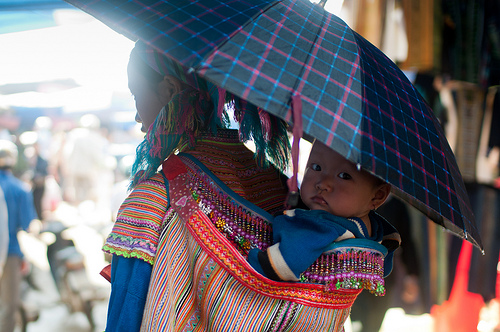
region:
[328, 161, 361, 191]
eye of the kid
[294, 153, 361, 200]
two eyes of the kid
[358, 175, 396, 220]
ear of the kid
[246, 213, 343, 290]
outfit on the kid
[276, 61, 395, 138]
umbrella above the kid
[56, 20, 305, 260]
person carrying a kid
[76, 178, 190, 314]
left arm of lady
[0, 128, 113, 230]
light in the background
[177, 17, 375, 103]
top of the umbrella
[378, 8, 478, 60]
blurry background of photo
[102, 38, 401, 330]
Woman carrying a child on her back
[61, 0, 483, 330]
Woman and a baby under an umbrella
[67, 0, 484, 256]
Plastic black umbrella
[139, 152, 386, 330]
Colorful beaded baby carrier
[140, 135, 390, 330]
Baby in a baby carrier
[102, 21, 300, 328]
Woman wearing a colorful shirt and blue sleeve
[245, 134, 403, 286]
Baby wearing a blue outfit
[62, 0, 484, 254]
Black umbrella with red and blue stripes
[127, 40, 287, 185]
Bandanna tied around a woman's head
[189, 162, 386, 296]
Fuchsia and flower beading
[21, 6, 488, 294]
mother and child under open umbrella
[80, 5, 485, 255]
blue and red plaid on black background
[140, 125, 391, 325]
baby being carried in pouch on mother's back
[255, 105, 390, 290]
baby in blue outfit with head turned to side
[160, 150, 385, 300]
colorful rows of hanging beadwork along pouch edge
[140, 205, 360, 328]
multi-colored thin stripes and borders on pouch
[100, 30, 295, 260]
mother in colorful scarf and shawl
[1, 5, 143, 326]
moving people in bright light ahead of mother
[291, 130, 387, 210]
baby with dark eyes and small lips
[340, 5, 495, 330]
person and shapes in low light behind baby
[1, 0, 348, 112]
sunlight in daytime sky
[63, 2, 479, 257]
top of open umbrella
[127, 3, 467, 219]
red and blue plaid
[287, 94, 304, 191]
red ribbon on umbrella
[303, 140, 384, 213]
baby looking at camera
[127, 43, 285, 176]
scarf tied to woman's head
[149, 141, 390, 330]
baby inside of bag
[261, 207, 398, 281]
blue top on baby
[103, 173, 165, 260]
stripes on woman's sleeve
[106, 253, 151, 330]
long sleeve of blue shirt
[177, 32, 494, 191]
BLUE UMBRELLA OPENED UP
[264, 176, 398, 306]
BLUE OUTFIT ON SMALL BABY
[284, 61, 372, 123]
PURPLE AND BLUE CHECKERS ON UMBRELLA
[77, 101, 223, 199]
BLUE YARN HANGING ON WOMAN'S HEAD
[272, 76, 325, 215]
PURPLE RIBBON ON UMBRELLA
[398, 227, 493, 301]
BLURRY RED OBJECT ON GROUND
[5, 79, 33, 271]
PERSON IN BLUE SHIRT IN BACKGROUND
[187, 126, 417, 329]
BABY IN BASKET ON WOMAN'S BACK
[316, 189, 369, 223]
CHEEK OF SMALL BABY